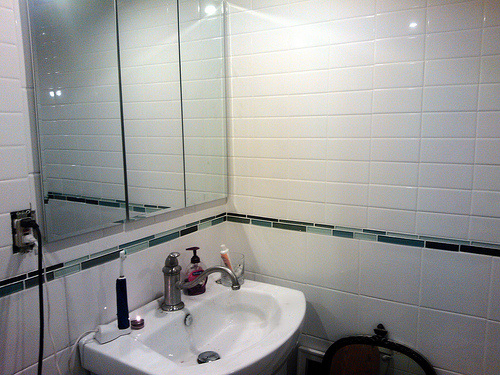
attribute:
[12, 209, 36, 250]
outlet — electrical, without cover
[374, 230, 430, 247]
green tile — striped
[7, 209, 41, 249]
eletrical outlet — electrical, without cover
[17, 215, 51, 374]
cord — black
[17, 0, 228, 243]
mirror cabinet — three door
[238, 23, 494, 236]
tiles — white, subway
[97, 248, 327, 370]
sink — bathroom, white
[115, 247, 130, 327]
toothbrush — electric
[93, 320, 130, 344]
base — white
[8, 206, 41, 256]
outlet — electrical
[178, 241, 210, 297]
bottle — purple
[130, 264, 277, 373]
sink drain — bathroom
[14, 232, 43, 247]
outlet — FULL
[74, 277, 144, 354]
drinking glass — clear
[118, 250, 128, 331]
toothbrush — electric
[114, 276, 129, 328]
handle — blue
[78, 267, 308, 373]
sink — white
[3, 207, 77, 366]
cord — WHITE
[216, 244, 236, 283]
tube — toothpaste